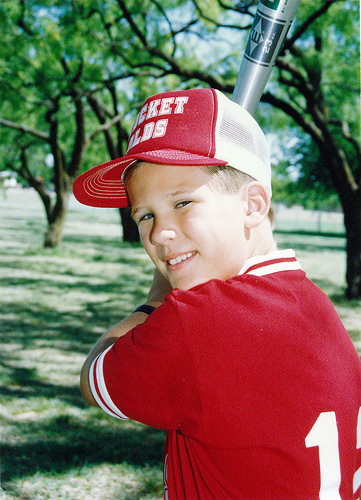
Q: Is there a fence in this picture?
A: No, there are no fences.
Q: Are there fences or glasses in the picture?
A: No, there are no fences or glasses.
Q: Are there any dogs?
A: No, there are no dogs.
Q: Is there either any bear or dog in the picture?
A: No, there are no dogs or bears.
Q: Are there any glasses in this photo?
A: No, there are no glasses.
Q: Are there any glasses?
A: No, there are no glasses.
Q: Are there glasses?
A: No, there are no glasses.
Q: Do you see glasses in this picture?
A: No, there are no glasses.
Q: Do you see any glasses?
A: No, there are no glasses.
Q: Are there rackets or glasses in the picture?
A: No, there are no glasses or rackets.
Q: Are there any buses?
A: No, there are no buses.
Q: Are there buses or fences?
A: No, there are no buses or fences.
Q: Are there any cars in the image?
A: No, there are no cars.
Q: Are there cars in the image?
A: No, there are no cars.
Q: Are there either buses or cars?
A: No, there are no cars or buses.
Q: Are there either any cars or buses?
A: No, there are no cars or buses.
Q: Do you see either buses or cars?
A: No, there are no cars or buses.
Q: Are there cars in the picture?
A: No, there are no cars.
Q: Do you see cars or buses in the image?
A: No, there are no cars or buses.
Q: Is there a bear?
A: No, there are no bears.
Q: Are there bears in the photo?
A: No, there are no bears.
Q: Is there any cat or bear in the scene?
A: No, there are no bears or cats.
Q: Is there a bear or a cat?
A: No, there are no bears or cats.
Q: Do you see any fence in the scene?
A: No, there are no fences.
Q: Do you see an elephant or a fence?
A: No, there are no fences or elephants.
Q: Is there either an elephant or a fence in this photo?
A: No, there are no fences or elephants.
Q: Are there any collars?
A: Yes, there is a collar.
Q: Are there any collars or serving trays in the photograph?
A: Yes, there is a collar.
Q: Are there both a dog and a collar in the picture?
A: No, there is a collar but no dogs.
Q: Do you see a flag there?
A: No, there are no flags.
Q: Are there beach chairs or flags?
A: No, there are no flags or beach chairs.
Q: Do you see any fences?
A: No, there are no fences.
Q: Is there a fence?
A: No, there are no fences.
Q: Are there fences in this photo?
A: No, there are no fences.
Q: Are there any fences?
A: No, there are no fences.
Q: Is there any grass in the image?
A: Yes, there is grass.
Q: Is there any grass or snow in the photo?
A: Yes, there is grass.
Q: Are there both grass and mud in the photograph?
A: No, there is grass but no mud.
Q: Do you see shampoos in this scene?
A: No, there are no shampoos.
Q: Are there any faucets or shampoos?
A: No, there are no shampoos or faucets.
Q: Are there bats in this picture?
A: Yes, there is a bat.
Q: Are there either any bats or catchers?
A: Yes, there is a bat.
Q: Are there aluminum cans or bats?
A: Yes, there is an aluminum bat.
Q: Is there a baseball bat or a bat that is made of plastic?
A: No, there is a bat but it is made of aluminum.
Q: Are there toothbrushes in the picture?
A: No, there are no toothbrushes.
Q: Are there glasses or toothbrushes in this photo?
A: No, there are no toothbrushes or glasses.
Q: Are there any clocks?
A: No, there are no clocks.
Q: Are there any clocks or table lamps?
A: No, there are no clocks or table lamps.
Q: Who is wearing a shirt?
A: The boy is wearing a shirt.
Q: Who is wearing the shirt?
A: The boy is wearing a shirt.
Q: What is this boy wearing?
A: The boy is wearing a shirt.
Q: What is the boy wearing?
A: The boy is wearing a shirt.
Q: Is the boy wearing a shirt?
A: Yes, the boy is wearing a shirt.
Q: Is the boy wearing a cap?
A: No, the boy is wearing a shirt.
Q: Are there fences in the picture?
A: No, there are no fences.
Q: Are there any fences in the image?
A: No, there are no fences.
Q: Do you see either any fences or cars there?
A: No, there are no fences or cars.